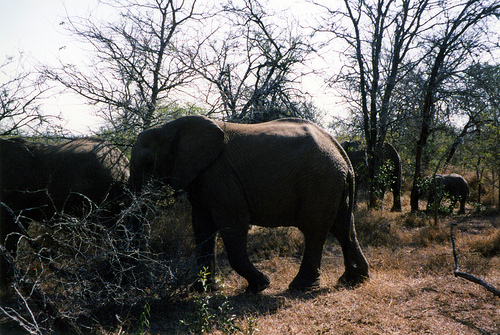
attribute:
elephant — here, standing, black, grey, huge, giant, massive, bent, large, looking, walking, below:
[138, 108, 401, 289]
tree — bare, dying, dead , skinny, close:
[101, 8, 237, 92]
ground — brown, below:
[305, 277, 446, 324]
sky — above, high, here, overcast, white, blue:
[20, 5, 98, 59]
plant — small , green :
[326, 62, 420, 190]